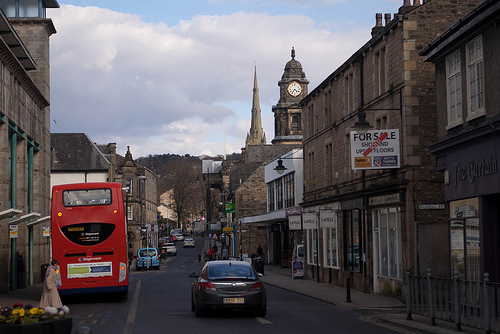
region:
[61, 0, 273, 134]
White clouds in blue sky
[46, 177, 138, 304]
Red bus on street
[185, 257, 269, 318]
Gray car driving in both lanes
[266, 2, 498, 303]
Buildings beside each other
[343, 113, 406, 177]
White sign on the building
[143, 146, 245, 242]
Mountain in the background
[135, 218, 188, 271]
Cars parked on the side of the street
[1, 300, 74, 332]
Flowers beside the street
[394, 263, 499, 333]
Gray metal post fence on the street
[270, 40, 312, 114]
Clock tower on top of building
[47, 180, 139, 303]
red passenger bus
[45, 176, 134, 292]
red bus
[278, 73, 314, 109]
white and black clock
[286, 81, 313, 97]
clock in tower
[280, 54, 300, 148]
clock tower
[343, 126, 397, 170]
red black and white sign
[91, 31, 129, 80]
white clouds in blue sky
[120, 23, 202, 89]
gray and white clouds in blue sky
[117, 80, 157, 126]
white clouds in blue sky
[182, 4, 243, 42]
white clouds in blue sky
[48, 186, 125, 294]
A bus on the street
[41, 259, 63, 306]
A person walking behind the bus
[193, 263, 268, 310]
A car near the bus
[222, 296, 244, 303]
The license plate behind the car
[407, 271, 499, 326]
A fence on the sidewalk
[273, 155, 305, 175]
A lamp connected to the building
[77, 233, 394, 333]
The street between the buildings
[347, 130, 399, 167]
A for sale sign on the buidling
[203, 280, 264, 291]
Tail lights on the car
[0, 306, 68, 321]
Flowers in a pot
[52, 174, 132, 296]
a red bus parked on the side of street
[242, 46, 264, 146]
a steeple on top of a church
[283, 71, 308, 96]
a clock on a building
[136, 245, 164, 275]
a blue van parked next to a curb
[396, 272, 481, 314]
a metal fence with post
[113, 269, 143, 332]
a yellow line painted on a street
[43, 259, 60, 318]
a woman wearing a long coat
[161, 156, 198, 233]
a tree with no leaves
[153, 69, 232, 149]
white clouds in the sky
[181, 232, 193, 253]
a white car on the road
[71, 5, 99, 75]
white clouds in blue sky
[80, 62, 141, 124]
white clouds in blue sky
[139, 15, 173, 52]
white clouds in blue sky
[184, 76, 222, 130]
white clouds in blue sky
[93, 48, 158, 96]
white clouds in blue sky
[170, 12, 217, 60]
white clouds in blue sky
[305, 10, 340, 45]
white clouds in blue sky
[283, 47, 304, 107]
clock tower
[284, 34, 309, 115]
brown clock tower